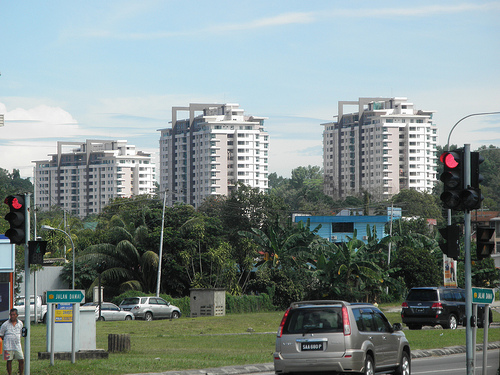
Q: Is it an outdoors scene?
A: Yes, it is outdoors.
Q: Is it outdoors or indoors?
A: It is outdoors.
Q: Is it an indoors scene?
A: No, it is outdoors.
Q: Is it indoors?
A: No, it is outdoors.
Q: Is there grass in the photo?
A: Yes, there is grass.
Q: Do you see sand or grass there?
A: Yes, there is grass.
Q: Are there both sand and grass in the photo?
A: No, there is grass but no sand.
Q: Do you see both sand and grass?
A: No, there is grass but no sand.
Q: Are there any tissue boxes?
A: No, there are no tissue boxes.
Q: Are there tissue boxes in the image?
A: No, there are no tissue boxes.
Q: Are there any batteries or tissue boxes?
A: No, there are no tissue boxes or batteries.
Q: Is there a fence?
A: No, there are no fences.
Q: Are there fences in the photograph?
A: No, there are no fences.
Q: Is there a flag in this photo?
A: No, there are no flags.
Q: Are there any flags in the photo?
A: No, there are no flags.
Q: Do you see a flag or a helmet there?
A: No, there are no flags or helmets.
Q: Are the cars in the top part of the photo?
A: No, the cars are in the bottom of the image.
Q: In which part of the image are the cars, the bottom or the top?
A: The cars are in the bottom of the image.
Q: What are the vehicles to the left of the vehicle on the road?
A: The vehicles are cars.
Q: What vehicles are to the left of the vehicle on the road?
A: The vehicles are cars.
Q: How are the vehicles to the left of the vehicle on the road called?
A: The vehicles are cars.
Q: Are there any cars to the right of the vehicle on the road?
A: No, the cars are to the left of the vehicle.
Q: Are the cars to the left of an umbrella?
A: No, the cars are to the left of a vehicle.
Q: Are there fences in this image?
A: No, there are no fences.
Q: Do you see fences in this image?
A: No, there are no fences.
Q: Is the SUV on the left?
A: No, the SUV is on the right of the image.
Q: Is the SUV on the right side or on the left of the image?
A: The SUV is on the right of the image.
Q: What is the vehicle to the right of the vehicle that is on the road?
A: The vehicle is a SUV.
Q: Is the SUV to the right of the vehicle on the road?
A: Yes, the SUV is to the right of the vehicle.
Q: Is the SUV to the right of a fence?
A: No, the SUV is to the right of the vehicle.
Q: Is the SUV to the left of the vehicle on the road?
A: No, the SUV is to the right of the vehicle.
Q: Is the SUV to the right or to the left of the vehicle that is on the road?
A: The SUV is to the right of the vehicle.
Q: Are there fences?
A: No, there are no fences.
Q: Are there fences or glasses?
A: No, there are no fences or glasses.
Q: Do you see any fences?
A: No, there are no fences.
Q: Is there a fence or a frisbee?
A: No, there are no fences or frisbees.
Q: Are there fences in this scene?
A: No, there are no fences.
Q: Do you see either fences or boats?
A: No, there are no fences or boats.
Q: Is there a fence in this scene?
A: No, there are no fences.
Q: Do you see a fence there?
A: No, there are no fences.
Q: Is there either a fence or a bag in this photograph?
A: No, there are no fences or bags.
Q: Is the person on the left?
A: Yes, the person is on the left of the image.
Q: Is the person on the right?
A: No, the person is on the left of the image.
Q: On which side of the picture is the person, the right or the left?
A: The person is on the left of the image.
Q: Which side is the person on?
A: The person is on the left of the image.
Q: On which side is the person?
A: The person is on the left of the image.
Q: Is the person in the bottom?
A: Yes, the person is in the bottom of the image.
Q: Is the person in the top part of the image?
A: No, the person is in the bottom of the image.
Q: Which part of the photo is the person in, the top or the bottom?
A: The person is in the bottom of the image.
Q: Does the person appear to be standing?
A: Yes, the person is standing.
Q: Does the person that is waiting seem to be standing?
A: Yes, the person is standing.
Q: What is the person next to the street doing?
A: The person is standing.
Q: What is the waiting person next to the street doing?
A: The person is standing.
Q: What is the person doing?
A: The person is standing.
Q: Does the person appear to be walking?
A: No, the person is standing.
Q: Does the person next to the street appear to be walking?
A: No, the person is standing.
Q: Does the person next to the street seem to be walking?
A: No, the person is standing.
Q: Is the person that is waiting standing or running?
A: The person is standing.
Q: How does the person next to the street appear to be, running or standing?
A: The person is standing.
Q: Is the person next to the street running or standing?
A: The person is standing.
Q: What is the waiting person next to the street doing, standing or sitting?
A: The person is standing.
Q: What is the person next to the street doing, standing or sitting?
A: The person is standing.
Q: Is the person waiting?
A: Yes, the person is waiting.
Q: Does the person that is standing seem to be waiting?
A: Yes, the person is waiting.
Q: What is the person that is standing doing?
A: The person is waiting.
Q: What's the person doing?
A: The person is waiting.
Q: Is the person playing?
A: No, the person is waiting.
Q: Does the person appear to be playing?
A: No, the person is waiting.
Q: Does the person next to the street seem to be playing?
A: No, the person is waiting.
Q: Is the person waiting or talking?
A: The person is waiting.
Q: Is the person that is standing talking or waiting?
A: The person is waiting.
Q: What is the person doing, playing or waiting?
A: The person is waiting.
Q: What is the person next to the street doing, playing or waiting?
A: The person is waiting.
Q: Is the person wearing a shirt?
A: Yes, the person is wearing a shirt.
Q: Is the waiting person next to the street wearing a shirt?
A: Yes, the person is wearing a shirt.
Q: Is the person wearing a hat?
A: No, the person is wearing a shirt.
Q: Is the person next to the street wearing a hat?
A: No, the person is wearing a shirt.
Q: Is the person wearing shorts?
A: Yes, the person is wearing shorts.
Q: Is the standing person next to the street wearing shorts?
A: Yes, the person is wearing shorts.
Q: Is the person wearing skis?
A: No, the person is wearing shorts.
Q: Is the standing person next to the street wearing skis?
A: No, the person is wearing shorts.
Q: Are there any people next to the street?
A: Yes, there is a person next to the street.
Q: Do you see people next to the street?
A: Yes, there is a person next to the street.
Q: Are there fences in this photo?
A: No, there are no fences.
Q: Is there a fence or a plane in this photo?
A: No, there are no fences or airplanes.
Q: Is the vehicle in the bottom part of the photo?
A: Yes, the vehicle is in the bottom of the image.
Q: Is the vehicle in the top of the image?
A: No, the vehicle is in the bottom of the image.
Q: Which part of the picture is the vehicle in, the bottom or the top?
A: The vehicle is in the bottom of the image.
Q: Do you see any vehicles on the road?
A: Yes, there is a vehicle on the road.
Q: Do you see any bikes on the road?
A: No, there is a vehicle on the road.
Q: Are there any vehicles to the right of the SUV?
A: No, the vehicle is to the left of the SUV.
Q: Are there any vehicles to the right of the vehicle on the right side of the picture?
A: No, the vehicle is to the left of the SUV.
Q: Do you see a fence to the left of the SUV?
A: No, there is a vehicle to the left of the SUV.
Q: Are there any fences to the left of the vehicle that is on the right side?
A: No, there is a vehicle to the left of the SUV.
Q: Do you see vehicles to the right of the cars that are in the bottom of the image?
A: Yes, there is a vehicle to the right of the cars.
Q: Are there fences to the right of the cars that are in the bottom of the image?
A: No, there is a vehicle to the right of the cars.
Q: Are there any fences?
A: No, there are no fences.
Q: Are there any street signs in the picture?
A: Yes, there is a street sign.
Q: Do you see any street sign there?
A: Yes, there is a street sign.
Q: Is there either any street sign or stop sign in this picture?
A: Yes, there is a street sign.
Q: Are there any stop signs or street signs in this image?
A: Yes, there is a street sign.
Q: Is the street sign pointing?
A: Yes, the street sign is pointing.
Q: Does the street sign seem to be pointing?
A: Yes, the street sign is pointing.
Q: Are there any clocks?
A: No, there are no clocks.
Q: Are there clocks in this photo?
A: No, there are no clocks.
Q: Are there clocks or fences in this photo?
A: No, there are no clocks or fences.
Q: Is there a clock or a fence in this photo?
A: No, there are no clocks or fences.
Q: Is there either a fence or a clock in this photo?
A: No, there are no clocks or fences.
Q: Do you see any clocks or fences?
A: No, there are no clocks or fences.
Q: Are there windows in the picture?
A: Yes, there are windows.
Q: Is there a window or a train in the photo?
A: Yes, there are windows.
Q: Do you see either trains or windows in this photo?
A: Yes, there are windows.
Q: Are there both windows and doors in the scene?
A: No, there are windows but no doors.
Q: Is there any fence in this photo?
A: No, there are no fences.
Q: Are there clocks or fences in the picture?
A: No, there are no fences or clocks.